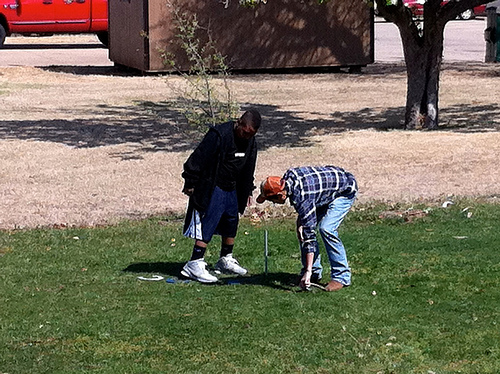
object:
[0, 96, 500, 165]
shadow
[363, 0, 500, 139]
tree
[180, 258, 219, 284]
color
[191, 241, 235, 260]
socks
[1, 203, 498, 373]
grass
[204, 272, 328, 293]
shadow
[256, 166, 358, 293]
person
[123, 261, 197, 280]
shadow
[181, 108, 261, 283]
person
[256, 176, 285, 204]
cap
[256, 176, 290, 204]
head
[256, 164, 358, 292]
shirt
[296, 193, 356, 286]
jeans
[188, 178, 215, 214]
pocket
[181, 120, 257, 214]
jacket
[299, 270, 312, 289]
ground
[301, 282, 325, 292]
touched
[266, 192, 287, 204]
down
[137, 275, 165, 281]
horseshoe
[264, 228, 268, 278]
pole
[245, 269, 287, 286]
ground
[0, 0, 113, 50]
vehicle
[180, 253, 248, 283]
shoes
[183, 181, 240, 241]
shorts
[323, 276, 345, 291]
shoe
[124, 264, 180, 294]
ground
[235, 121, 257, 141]
down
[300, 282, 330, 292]
horseshoe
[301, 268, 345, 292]
boots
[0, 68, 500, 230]
grass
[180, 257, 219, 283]
sneaker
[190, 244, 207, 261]
sock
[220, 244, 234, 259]
sock